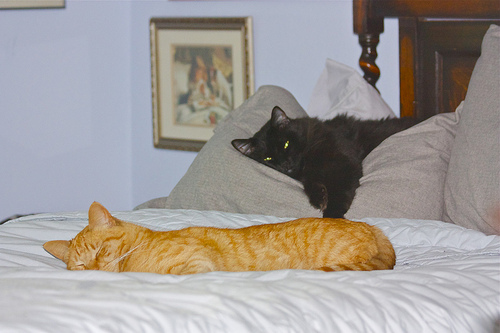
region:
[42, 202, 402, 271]
an orange cat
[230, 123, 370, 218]
a black cat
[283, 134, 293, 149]
the left eye of the cat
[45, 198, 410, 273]
the cat is sleep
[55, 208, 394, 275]
cat is laying on the bed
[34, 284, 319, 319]
the comforter is white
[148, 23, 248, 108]
picture on the wall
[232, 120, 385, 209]
cat is laying on the pillow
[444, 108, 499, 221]
a pillow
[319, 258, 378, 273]
the cats tail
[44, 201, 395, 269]
yellow cat laying comfortably on bed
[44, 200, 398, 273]
cat is fast asleep on bottom of bed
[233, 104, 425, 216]
black cat is laying directly on a pillow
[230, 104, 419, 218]
felines eyes are open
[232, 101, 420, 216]
black cat is observing photographer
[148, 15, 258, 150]
picture frame hanging beside bed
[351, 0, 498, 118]
wood headboard of bed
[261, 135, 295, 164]
green eyes are looking into my soul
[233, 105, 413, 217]
jet black cats furr coat looks soft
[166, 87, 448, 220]
pillows with matching pillow cases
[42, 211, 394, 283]
a yellow cat on a bed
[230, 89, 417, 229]
a black cat on a pillow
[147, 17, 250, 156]
a window on a wall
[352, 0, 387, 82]
a wooden spinal on a bed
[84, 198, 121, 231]
a cat left ear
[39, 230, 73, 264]
a yellow cat ear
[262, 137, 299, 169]
green cat eyes on a black cat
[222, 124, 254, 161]
a right black ear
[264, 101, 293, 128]
a left black ear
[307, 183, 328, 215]
a right cat paw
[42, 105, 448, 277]
An orange cat and a black cat are laying on a bed.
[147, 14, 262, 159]
A piece of framed art is on the wall.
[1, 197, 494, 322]
The sheets on the bed are white in color.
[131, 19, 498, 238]
The pillows on the bed are grey in color.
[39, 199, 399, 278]
The orange cat is sleeping on the white sheets on the bed.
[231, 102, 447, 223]
The black cat is laying on the grey pillow on the bed.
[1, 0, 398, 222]
The wall is painted a light blue color.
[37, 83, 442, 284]
Two cats on a bed.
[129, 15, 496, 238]
Three pillows on a bed.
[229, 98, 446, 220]
Black cat with yellow open eyes on a bed.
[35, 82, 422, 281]
Two cats in the image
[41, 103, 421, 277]
Two cats laying down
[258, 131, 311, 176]
Cat in the background eyes are green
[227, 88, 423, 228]
Cat's fur is black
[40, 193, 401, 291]
Cat's fur is orange in color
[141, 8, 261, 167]
A picture frame in the background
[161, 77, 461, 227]
Cat is laying on a pillow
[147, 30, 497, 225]
The pillows are gray in color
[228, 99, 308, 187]
Cat is looking at the camera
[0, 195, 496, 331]
Cat is sleeping on a white blanket